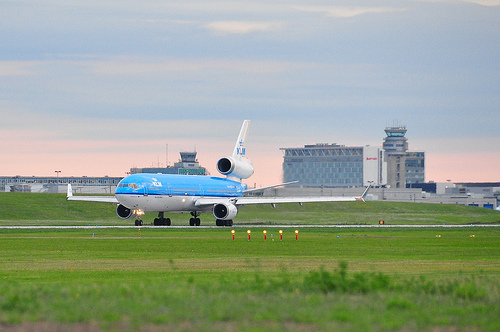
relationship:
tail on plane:
[222, 120, 251, 178] [57, 122, 368, 231]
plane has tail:
[66, 119, 300, 225] [227, 105, 272, 183]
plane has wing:
[66, 119, 300, 225] [239, 182, 381, 214]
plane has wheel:
[66, 119, 300, 225] [213, 216, 236, 227]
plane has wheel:
[66, 119, 300, 225] [185, 214, 204, 229]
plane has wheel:
[66, 119, 300, 225] [151, 212, 171, 230]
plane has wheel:
[66, 119, 300, 225] [131, 210, 143, 230]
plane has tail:
[66, 119, 300, 225] [216, 112, 266, 188]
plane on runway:
[58, 117, 301, 224] [3, 218, 499, 228]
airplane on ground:
[58, 110, 303, 230] [117, 217, 272, 240]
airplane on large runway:
[58, 110, 303, 230] [1, 212, 498, 244]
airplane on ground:
[58, 110, 303, 230] [0, 212, 499, 330]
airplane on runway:
[58, 110, 303, 230] [0, 220, 499, 230]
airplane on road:
[58, 110, 303, 230] [53, 222, 278, 247]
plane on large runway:
[66, 119, 300, 225] [0, 224, 497, 228]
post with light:
[291, 224, 299, 240] [292, 224, 300, 233]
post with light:
[273, 224, 284, 238] [278, 227, 285, 234]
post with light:
[258, 225, 269, 240] [259, 227, 266, 235]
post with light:
[242, 224, 254, 243] [246, 225, 253, 236]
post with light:
[229, 227, 241, 243] [229, 224, 239, 238]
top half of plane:
[115, 175, 245, 201] [112, 170, 302, 195]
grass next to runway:
[13, 194, 498, 329] [0, 220, 498, 234]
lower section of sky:
[0, 140, 498, 190] [0, 0, 498, 190]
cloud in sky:
[0, 0, 499, 184] [0, 0, 498, 190]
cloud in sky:
[149, 12, 273, 39] [338, 42, 435, 119]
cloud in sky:
[0, 0, 499, 184] [338, 42, 435, 119]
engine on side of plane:
[212, 201, 237, 222] [58, 117, 301, 224]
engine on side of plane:
[115, 202, 132, 219] [58, 117, 301, 224]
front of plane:
[111, 176, 151, 215] [64, 121, 287, 225]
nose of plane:
[113, 173, 144, 215] [58, 117, 301, 224]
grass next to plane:
[13, 194, 498, 329] [66, 115, 307, 236]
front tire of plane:
[133, 217, 144, 227] [65, 132, 365, 239]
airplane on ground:
[58, 110, 303, 230] [2, 184, 499, 330]